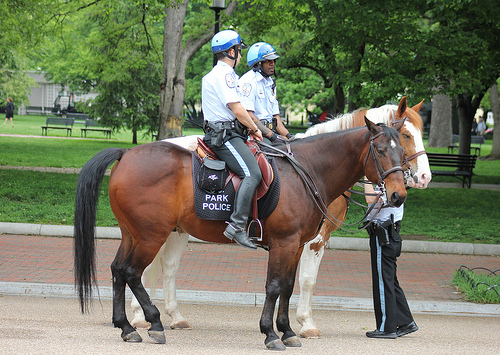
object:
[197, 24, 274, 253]
policeman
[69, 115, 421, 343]
horse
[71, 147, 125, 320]
tail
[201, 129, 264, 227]
pants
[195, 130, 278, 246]
saddle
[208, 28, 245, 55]
helmet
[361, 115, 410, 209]
head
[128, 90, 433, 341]
horse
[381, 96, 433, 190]
head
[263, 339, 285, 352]
hoof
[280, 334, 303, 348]
hoof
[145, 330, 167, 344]
hoof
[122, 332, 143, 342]
hoof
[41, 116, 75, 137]
bench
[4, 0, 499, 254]
park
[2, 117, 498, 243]
grass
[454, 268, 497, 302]
weeds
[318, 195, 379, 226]
harness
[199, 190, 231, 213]
park police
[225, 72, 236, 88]
insignia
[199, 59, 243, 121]
shirt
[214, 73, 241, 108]
sleeve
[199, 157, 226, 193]
bag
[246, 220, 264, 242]
stirrup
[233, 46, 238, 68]
strap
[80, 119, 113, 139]
bench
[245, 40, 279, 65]
helmet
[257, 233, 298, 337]
leg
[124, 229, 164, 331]
leg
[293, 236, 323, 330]
leg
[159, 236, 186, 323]
leg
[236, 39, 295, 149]
policeman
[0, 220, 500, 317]
street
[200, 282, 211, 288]
brick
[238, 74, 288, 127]
shirt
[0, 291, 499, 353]
sidewalk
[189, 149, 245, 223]
sign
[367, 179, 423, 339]
officer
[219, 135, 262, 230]
leg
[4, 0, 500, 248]
background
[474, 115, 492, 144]
person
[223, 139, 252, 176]
stripe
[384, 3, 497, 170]
tree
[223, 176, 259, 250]
boots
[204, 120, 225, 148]
firearm